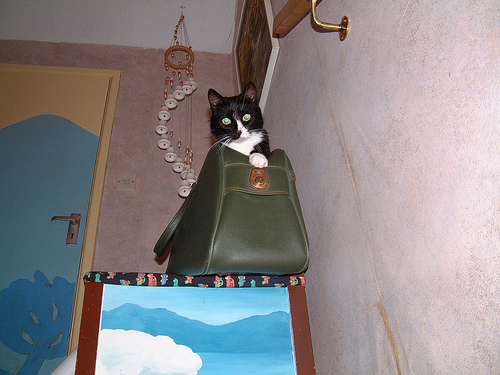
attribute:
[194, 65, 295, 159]
cat — black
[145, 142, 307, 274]
purse — green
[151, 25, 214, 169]
chime — wind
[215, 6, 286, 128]
frame — white, framed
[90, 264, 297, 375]
door — blue, painted, push, post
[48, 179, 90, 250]
knob — door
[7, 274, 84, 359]
tree — blue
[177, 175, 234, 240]
fabric — black, patterned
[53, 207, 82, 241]
handle — silver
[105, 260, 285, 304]
blanket — blue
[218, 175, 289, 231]
bag — green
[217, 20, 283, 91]
painting — framed